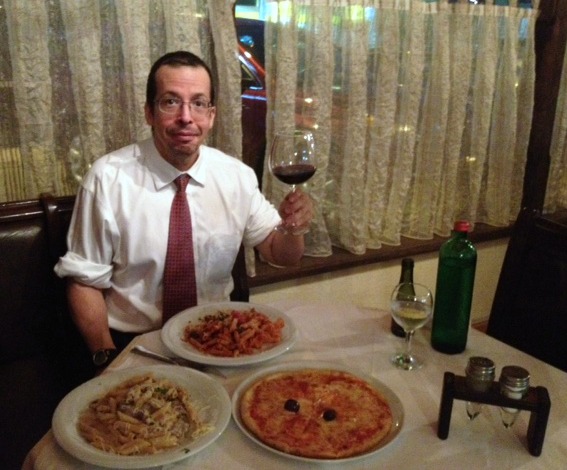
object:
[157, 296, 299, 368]
plate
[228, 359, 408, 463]
plate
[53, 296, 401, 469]
dining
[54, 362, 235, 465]
plate